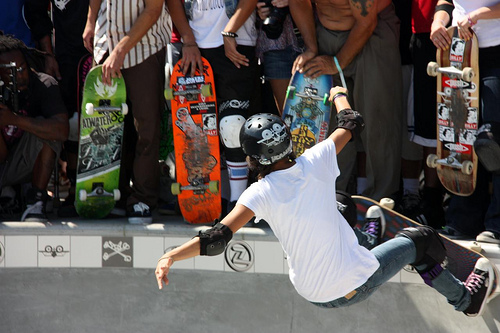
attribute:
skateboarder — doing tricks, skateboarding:
[149, 78, 500, 320]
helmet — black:
[237, 112, 300, 169]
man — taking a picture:
[0, 31, 73, 223]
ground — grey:
[3, 210, 499, 333]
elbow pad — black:
[197, 214, 238, 258]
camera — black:
[253, 1, 291, 42]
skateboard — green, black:
[76, 60, 130, 218]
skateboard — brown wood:
[425, 22, 484, 202]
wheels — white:
[79, 102, 128, 204]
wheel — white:
[378, 195, 397, 212]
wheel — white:
[464, 240, 480, 252]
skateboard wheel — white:
[425, 55, 441, 80]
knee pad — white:
[216, 109, 251, 153]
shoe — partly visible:
[357, 204, 386, 245]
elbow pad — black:
[329, 103, 372, 143]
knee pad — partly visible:
[329, 188, 361, 231]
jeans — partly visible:
[430, 69, 500, 246]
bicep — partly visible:
[48, 105, 73, 125]